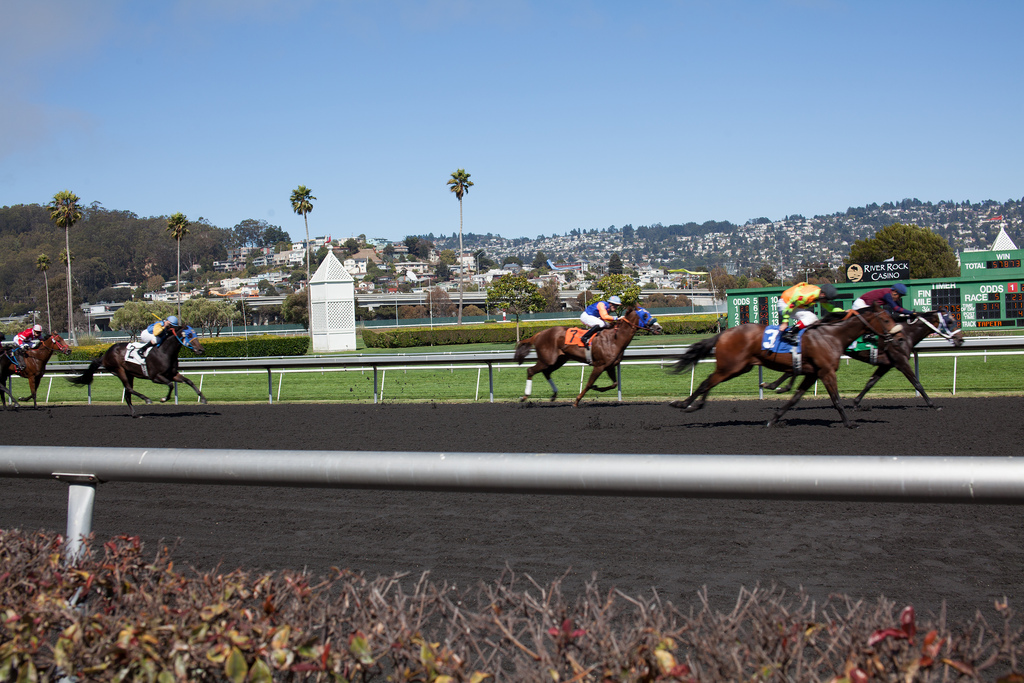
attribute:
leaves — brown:
[4, 522, 972, 670]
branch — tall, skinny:
[48, 187, 81, 246]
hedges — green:
[15, 321, 1011, 360]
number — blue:
[750, 341, 817, 380]